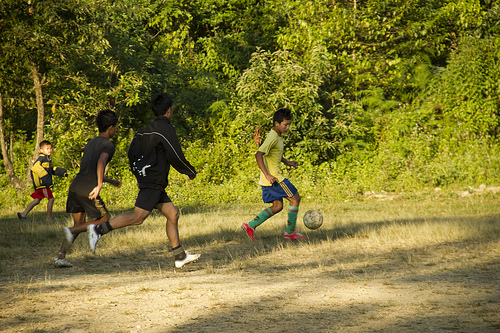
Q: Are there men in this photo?
A: No, there are no men.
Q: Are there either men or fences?
A: No, there are no men or fences.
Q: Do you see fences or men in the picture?
A: No, there are no men or fences.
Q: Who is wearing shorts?
A: The boy is wearing shorts.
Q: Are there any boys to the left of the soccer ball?
A: Yes, there is a boy to the left of the soccer ball.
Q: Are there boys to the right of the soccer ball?
A: No, the boy is to the left of the soccer ball.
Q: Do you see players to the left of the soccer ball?
A: No, there is a boy to the left of the soccer ball.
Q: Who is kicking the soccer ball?
A: The boy is kicking the soccer ball.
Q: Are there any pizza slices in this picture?
A: No, there are no pizza slices.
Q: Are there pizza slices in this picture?
A: No, there are no pizza slices.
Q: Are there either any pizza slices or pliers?
A: No, there are no pizza slices or pliers.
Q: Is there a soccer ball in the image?
A: Yes, there is a soccer ball.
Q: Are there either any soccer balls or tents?
A: Yes, there is a soccer ball.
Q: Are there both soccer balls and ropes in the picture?
A: No, there is a soccer ball but no ropes.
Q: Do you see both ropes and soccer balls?
A: No, there is a soccer ball but no ropes.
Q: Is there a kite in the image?
A: No, there are no kites.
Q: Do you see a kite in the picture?
A: No, there are no kites.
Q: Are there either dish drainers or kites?
A: No, there are no kites or dish drainers.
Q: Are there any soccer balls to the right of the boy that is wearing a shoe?
A: Yes, there is a soccer ball to the right of the boy.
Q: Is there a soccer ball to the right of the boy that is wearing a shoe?
A: Yes, there is a soccer ball to the right of the boy.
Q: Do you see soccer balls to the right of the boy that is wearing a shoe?
A: Yes, there is a soccer ball to the right of the boy.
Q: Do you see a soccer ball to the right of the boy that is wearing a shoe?
A: Yes, there is a soccer ball to the right of the boy.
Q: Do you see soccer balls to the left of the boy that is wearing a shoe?
A: No, the soccer ball is to the right of the boy.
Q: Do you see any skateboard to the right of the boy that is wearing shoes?
A: No, there is a soccer ball to the right of the boy.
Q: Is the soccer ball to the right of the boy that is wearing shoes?
A: Yes, the soccer ball is to the right of the boy.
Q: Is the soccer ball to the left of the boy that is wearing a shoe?
A: No, the soccer ball is to the right of the boy.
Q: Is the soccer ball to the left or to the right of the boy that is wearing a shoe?
A: The soccer ball is to the right of the boy.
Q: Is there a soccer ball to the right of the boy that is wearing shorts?
A: Yes, there is a soccer ball to the right of the boy.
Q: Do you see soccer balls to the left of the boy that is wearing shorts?
A: No, the soccer ball is to the right of the boy.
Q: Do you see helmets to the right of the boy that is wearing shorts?
A: No, there is a soccer ball to the right of the boy.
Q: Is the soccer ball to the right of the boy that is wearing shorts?
A: Yes, the soccer ball is to the right of the boy.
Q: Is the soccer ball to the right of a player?
A: No, the soccer ball is to the right of the boy.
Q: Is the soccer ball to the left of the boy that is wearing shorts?
A: No, the soccer ball is to the right of the boy.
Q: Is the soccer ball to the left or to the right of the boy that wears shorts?
A: The soccer ball is to the right of the boy.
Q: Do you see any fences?
A: No, there are no fences.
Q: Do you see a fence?
A: No, there are no fences.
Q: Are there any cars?
A: No, there are no cars.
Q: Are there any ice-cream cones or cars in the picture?
A: No, there are no cars or ice-cream cones.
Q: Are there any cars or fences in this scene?
A: No, there are no fences or cars.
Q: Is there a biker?
A: No, there are no bikers.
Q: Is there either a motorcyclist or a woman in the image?
A: No, there are no bikers or women.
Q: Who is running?
A: The boy is running.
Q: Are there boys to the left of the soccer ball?
A: Yes, there is a boy to the left of the soccer ball.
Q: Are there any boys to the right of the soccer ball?
A: No, the boy is to the left of the soccer ball.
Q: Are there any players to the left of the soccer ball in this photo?
A: No, there is a boy to the left of the soccer ball.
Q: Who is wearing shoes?
A: The boy is wearing shoes.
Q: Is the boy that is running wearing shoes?
A: Yes, the boy is wearing shoes.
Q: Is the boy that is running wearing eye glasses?
A: No, the boy is wearing shoes.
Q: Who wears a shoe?
A: The boy wears a shoe.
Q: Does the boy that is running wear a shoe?
A: Yes, the boy wears a shoe.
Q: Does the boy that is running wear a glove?
A: No, the boy wears a shoe.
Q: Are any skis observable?
A: No, there are no skis.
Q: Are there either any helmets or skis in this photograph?
A: No, there are no skis or helmets.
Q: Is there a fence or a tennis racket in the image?
A: No, there are no fences or rackets.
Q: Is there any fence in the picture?
A: No, there are no fences.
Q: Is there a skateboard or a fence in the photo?
A: No, there are no fences or skateboards.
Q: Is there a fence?
A: No, there are no fences.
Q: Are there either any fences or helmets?
A: No, there are no fences or helmets.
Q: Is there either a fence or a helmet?
A: No, there are no fences or helmets.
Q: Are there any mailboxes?
A: No, there are no mailboxes.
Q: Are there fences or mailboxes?
A: No, there are no mailboxes or fences.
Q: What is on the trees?
A: The leaves are on the trees.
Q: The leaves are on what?
A: The leaves are on the trees.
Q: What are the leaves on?
A: The leaves are on the trees.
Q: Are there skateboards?
A: No, there are no skateboards.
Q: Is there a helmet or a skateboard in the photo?
A: No, there are no skateboards or helmets.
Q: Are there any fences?
A: No, there are no fences.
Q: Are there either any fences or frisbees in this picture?
A: No, there are no fences or frisbees.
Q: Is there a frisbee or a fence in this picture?
A: No, there are no fences or frisbees.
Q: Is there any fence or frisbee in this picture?
A: No, there are no fences or frisbees.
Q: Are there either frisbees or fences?
A: No, there are no fences or frisbees.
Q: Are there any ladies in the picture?
A: No, there are no ladies.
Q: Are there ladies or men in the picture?
A: No, there are no ladies or men.